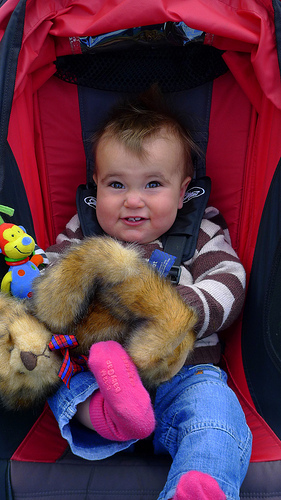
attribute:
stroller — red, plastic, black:
[2, 3, 279, 498]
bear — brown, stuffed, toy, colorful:
[0, 233, 196, 408]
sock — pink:
[84, 339, 158, 443]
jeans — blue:
[48, 358, 254, 497]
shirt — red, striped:
[51, 200, 247, 366]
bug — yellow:
[0, 206, 44, 298]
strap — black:
[154, 173, 211, 281]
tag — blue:
[148, 250, 178, 273]